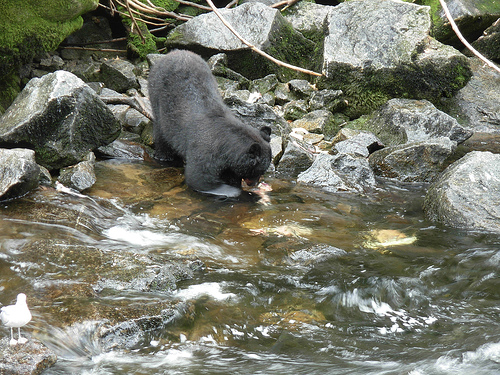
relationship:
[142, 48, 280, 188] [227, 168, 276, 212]
bear catching h next meal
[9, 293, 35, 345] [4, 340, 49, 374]
bird sitting on a stone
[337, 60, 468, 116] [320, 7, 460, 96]
moss growing on a rock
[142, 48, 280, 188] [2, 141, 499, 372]
bear in water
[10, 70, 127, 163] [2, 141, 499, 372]
rock in water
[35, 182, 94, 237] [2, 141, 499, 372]
stone under water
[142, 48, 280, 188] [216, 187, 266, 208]
bear has paws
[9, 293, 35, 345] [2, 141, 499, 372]
bird by water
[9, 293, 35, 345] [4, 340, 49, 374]
bird standing on a stone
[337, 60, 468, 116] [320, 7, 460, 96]
moss on rock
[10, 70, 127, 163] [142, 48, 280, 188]
rock next to bear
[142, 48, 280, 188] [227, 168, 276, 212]
bear trying to catch h next meal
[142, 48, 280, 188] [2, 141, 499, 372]
bear at edge of water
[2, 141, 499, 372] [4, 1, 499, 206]
water lined with rocks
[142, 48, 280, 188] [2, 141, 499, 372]
bear standing in water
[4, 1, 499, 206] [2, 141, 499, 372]
rocks eroded by water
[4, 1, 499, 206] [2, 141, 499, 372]
rocks by water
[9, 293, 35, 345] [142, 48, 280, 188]
bird near bear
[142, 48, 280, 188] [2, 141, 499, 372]
bear fishing in water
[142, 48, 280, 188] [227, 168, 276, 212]
bear looking for h next meal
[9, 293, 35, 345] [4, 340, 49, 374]
bird on a stone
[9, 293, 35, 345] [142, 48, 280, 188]
bird watching bear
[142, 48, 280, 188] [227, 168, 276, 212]
bear trying to catch next meal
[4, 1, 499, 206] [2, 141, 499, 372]
rocks on shore of water